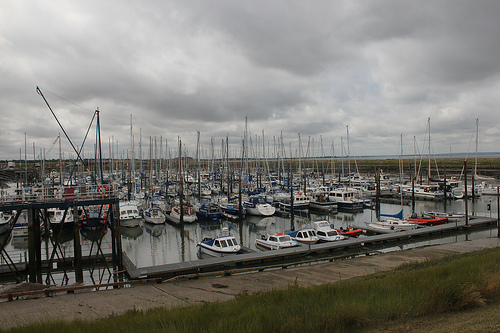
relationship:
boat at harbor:
[195, 233, 257, 261] [1, 237, 500, 330]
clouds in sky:
[3, 1, 499, 156] [1, 1, 500, 164]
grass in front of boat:
[2, 245, 500, 331] [195, 233, 257, 261]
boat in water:
[256, 229, 299, 254] [2, 179, 500, 301]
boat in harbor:
[286, 225, 321, 245] [1, 237, 500, 330]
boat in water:
[336, 220, 363, 239] [2, 179, 500, 301]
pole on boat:
[288, 180, 303, 234] [286, 225, 321, 245]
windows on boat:
[217, 237, 238, 247] [195, 233, 257, 261]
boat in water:
[195, 233, 257, 261] [2, 179, 500, 301]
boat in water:
[286, 225, 321, 245] [2, 179, 500, 301]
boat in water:
[305, 219, 351, 244] [2, 179, 500, 301]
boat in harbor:
[336, 220, 363, 239] [1, 237, 500, 330]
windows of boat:
[217, 237, 238, 247] [195, 233, 257, 261]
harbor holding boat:
[1, 237, 500, 330] [195, 233, 257, 261]